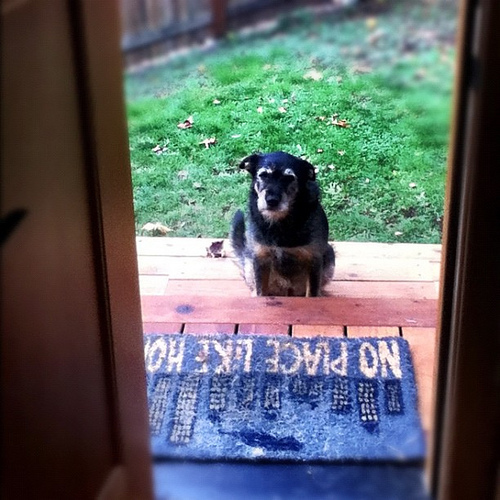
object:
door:
[0, 1, 158, 498]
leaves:
[304, 66, 322, 80]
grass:
[404, 95, 421, 114]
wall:
[454, 384, 498, 499]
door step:
[136, 294, 451, 468]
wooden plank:
[143, 294, 437, 327]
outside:
[150, 4, 431, 442]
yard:
[128, 12, 434, 233]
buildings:
[169, 375, 203, 446]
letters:
[166, 333, 188, 372]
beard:
[261, 211, 285, 225]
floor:
[135, 236, 442, 500]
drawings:
[147, 372, 409, 448]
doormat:
[140, 332, 426, 465]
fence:
[118, 3, 215, 48]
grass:
[138, 72, 159, 89]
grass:
[408, 207, 428, 234]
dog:
[231, 152, 337, 297]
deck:
[136, 294, 442, 492]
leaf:
[200, 138, 215, 148]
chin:
[263, 213, 278, 222]